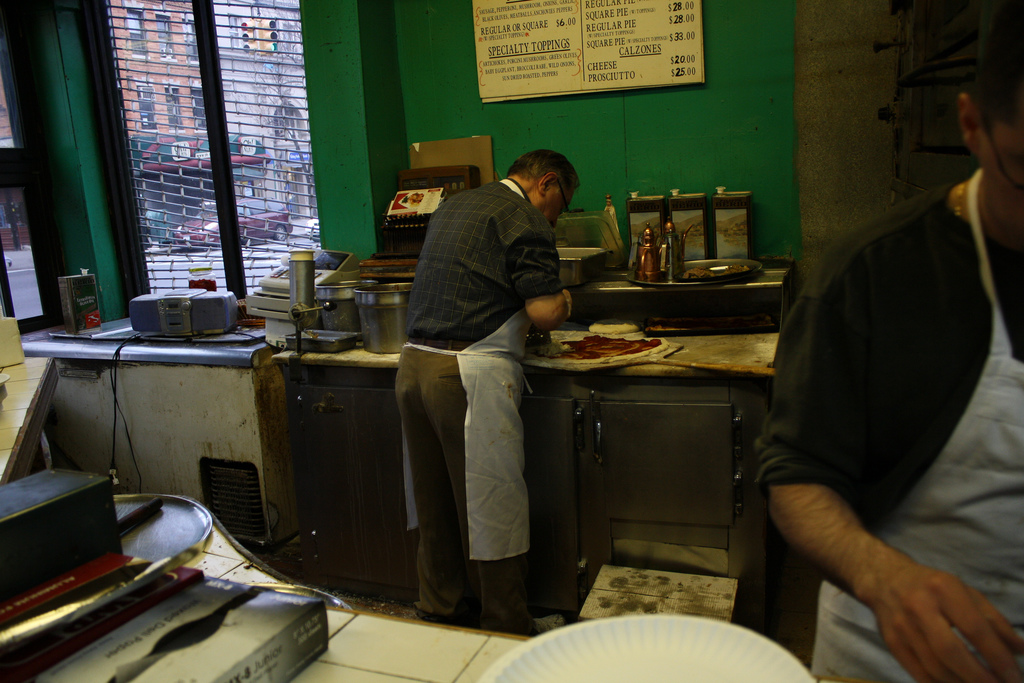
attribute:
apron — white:
[814, 167, 1014, 680]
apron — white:
[405, 300, 529, 570]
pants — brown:
[394, 341, 534, 629]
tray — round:
[620, 231, 761, 286]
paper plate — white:
[474, 608, 829, 679]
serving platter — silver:
[616, 250, 775, 285]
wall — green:
[619, 114, 796, 176]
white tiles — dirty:
[571, 556, 740, 629]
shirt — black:
[404, 185, 565, 333]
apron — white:
[445, 325, 566, 576]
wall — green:
[648, 116, 748, 162]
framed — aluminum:
[73, 6, 130, 261]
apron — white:
[449, 325, 525, 567]